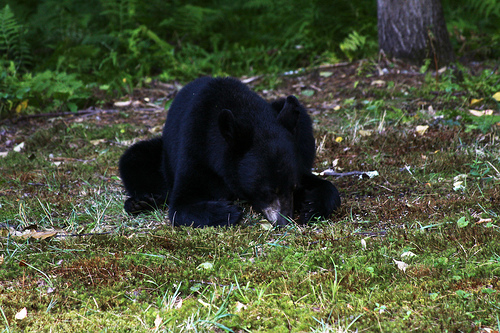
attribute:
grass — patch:
[2, 62, 491, 329]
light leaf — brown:
[14, 226, 58, 243]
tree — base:
[377, 1, 451, 70]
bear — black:
[101, 45, 356, 235]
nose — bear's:
[255, 212, 298, 234]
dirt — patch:
[282, 61, 426, 93]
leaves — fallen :
[298, 87, 315, 97]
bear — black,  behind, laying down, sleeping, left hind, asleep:
[115, 71, 346, 233]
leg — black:
[119, 140, 165, 192]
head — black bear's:
[219, 97, 299, 224]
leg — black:
[93, 109, 198, 230]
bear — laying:
[97, 60, 360, 230]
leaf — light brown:
[451, 179, 463, 187]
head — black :
[213, 93, 305, 238]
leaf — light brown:
[9, 224, 59, 241]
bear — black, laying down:
[89, 35, 404, 242]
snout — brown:
[252, 188, 296, 247]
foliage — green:
[1, 2, 498, 127]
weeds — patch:
[1, 56, 498, 331]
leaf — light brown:
[389, 243, 420, 275]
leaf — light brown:
[449, 170, 471, 194]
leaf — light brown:
[84, 132, 108, 148]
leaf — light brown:
[369, 76, 390, 89]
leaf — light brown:
[392, 254, 413, 275]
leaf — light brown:
[399, 246, 421, 260]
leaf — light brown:
[10, 304, 31, 322]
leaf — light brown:
[3, 223, 65, 244]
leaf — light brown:
[228, 296, 250, 325]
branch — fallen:
[1, 211, 106, 258]